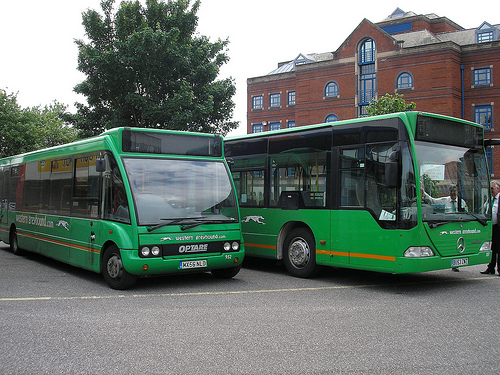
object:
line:
[0, 226, 101, 255]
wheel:
[282, 228, 319, 279]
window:
[416, 140, 490, 221]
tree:
[56, 0, 240, 138]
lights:
[151, 246, 159, 256]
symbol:
[56, 219, 71, 230]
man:
[479, 180, 500, 277]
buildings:
[247, 8, 500, 185]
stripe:
[245, 242, 396, 262]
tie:
[488, 198, 494, 217]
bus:
[0, 126, 246, 290]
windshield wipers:
[147, 216, 207, 232]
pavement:
[4, 285, 497, 375]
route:
[422, 118, 472, 147]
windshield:
[123, 158, 238, 224]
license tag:
[179, 260, 207, 270]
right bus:
[224, 111, 494, 278]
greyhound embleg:
[241, 215, 265, 225]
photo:
[0, 0, 500, 375]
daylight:
[0, 0, 500, 375]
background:
[0, 0, 499, 112]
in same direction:
[470, 30, 493, 177]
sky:
[0, 0, 500, 141]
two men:
[420, 178, 500, 276]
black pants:
[487, 219, 500, 269]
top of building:
[333, 7, 467, 56]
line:
[1, 274, 500, 301]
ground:
[0, 235, 500, 375]